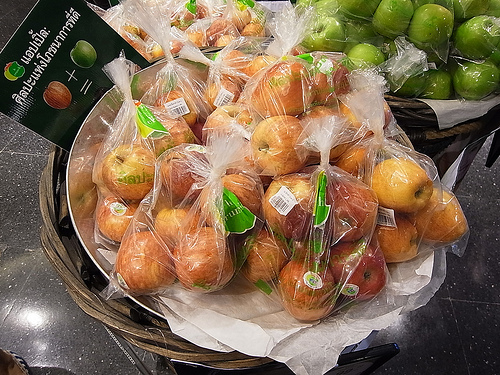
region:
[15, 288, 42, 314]
this is the table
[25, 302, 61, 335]
the table is black in color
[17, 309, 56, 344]
the table is shiny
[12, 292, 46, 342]
the table is clean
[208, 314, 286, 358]
this is a paper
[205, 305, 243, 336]
the paper is white in color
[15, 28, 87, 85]
this is a board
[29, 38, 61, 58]
these are some writings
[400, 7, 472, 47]
the fruits are green in color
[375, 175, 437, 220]
the fruits are orange in color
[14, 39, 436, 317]
food in the bag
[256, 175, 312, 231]
white tag on bag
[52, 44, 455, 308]
many round foods in bags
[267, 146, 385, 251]
plastic bag in photo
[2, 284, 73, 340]
light on the ground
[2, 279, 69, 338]
ground in the photo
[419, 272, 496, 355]
lines on the ground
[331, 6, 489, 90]
green food in bag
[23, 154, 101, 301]
edge of the basket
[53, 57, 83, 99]
plus sign on sign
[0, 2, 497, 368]
Fruit is in the supermarket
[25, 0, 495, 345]
The fruit is being sold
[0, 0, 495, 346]
The fruit is in bags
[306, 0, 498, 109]
These apples are green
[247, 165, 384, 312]
These apples are red and orange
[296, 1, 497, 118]
The apples are Granny Smith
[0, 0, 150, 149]
A sign is in the corner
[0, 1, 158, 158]
The sign explains the apple sale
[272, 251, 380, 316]
the apples have stickers on them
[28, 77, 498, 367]
The bags of apples are in baskets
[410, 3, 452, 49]
a bright green apple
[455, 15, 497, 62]
a bright green apple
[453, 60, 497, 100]
a bright green apple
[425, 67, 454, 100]
a bright green apple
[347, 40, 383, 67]
a bright green apple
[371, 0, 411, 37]
a bright green apple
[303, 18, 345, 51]
a bright green apple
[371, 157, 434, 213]
an orange red apple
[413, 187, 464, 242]
an orange red apple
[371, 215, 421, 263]
an orange red apple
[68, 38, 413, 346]
a basket full of apples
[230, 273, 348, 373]
apples are placed in a white paper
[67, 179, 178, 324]
the appls are on a tray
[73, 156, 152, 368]
the tray is on the basket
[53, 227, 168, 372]
the basket is weaven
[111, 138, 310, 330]
apples are red in color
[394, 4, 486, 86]
apple are green in color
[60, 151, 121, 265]
the tray is silvery incolor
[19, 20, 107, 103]
a book is in the basket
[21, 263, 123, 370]
the floor is mde of marble